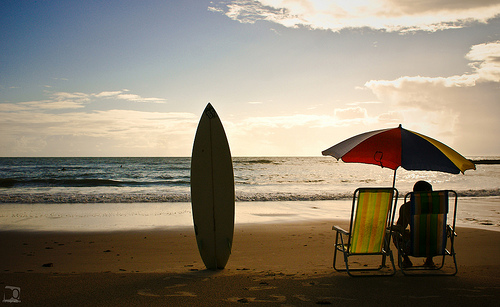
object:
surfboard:
[192, 104, 235, 270]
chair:
[332, 187, 395, 278]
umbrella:
[321, 124, 475, 268]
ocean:
[1, 156, 500, 202]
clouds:
[206, 0, 499, 31]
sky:
[0, 0, 500, 160]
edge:
[369, 45, 500, 117]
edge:
[190, 101, 234, 271]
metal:
[333, 246, 349, 253]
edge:
[3, 188, 498, 219]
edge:
[318, 150, 477, 175]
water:
[0, 156, 500, 204]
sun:
[236, 115, 334, 155]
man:
[393, 181, 439, 267]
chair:
[390, 190, 458, 276]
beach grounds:
[0, 196, 500, 307]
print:
[0, 266, 500, 307]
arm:
[331, 225, 350, 235]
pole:
[382, 169, 396, 267]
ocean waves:
[0, 157, 499, 202]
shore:
[0, 194, 499, 307]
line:
[0, 154, 499, 160]